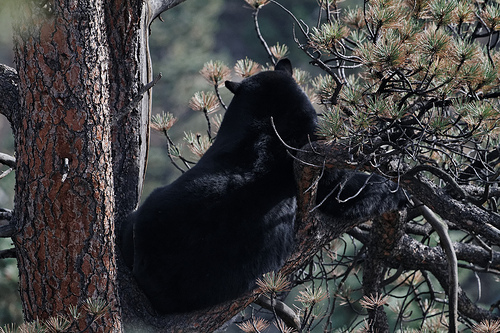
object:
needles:
[328, 10, 496, 72]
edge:
[119, 229, 217, 333]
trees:
[151, 7, 226, 75]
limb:
[415, 202, 456, 333]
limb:
[250, 279, 317, 331]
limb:
[400, 145, 477, 190]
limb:
[128, 61, 172, 93]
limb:
[456, 232, 498, 272]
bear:
[131, 57, 415, 315]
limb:
[110, 72, 161, 127]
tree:
[3, 2, 122, 331]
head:
[222, 59, 316, 132]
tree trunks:
[0, 0, 123, 333]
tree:
[107, 3, 146, 216]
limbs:
[295, 34, 480, 197]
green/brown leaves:
[311, 0, 498, 120]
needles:
[358, 47, 468, 153]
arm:
[327, 169, 405, 216]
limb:
[411, 195, 466, 332]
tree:
[311, 110, 482, 307]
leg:
[311, 165, 409, 220]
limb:
[287, 139, 494, 238]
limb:
[143, 66, 163, 93]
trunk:
[104, 1, 151, 238]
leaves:
[293, 2, 499, 172]